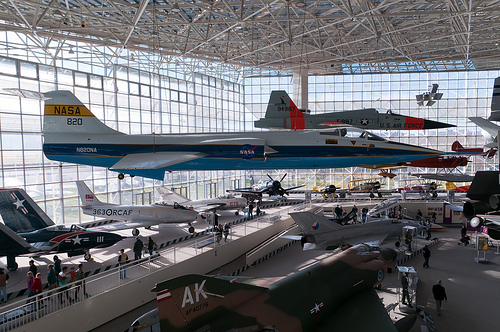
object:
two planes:
[74, 180, 249, 236]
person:
[32, 273, 47, 307]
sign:
[225, 172, 306, 200]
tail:
[41, 90, 128, 176]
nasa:
[45, 105, 95, 116]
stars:
[72, 235, 82, 246]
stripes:
[83, 237, 90, 241]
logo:
[65, 234, 90, 245]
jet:
[0, 187, 136, 270]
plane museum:
[56, 175, 435, 323]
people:
[43, 264, 61, 300]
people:
[133, 237, 145, 264]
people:
[215, 223, 223, 243]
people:
[352, 205, 359, 220]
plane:
[253, 90, 457, 130]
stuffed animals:
[73, 180, 199, 236]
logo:
[9, 192, 29, 215]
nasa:
[240, 144, 258, 161]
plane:
[155, 186, 249, 219]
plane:
[226, 172, 307, 198]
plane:
[345, 177, 385, 198]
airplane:
[254, 89, 457, 131]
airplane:
[39, 90, 484, 181]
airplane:
[280, 211, 428, 252]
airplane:
[149, 242, 387, 332]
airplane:
[76, 180, 199, 229]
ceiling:
[2, 1, 497, 72]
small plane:
[156, 187, 248, 217]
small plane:
[226, 173, 306, 198]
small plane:
[310, 184, 341, 198]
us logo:
[361, 118, 369, 126]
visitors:
[45, 264, 58, 299]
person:
[118, 249, 130, 280]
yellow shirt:
[119, 252, 127, 263]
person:
[431, 279, 448, 317]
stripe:
[43, 143, 444, 159]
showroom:
[0, 0, 500, 330]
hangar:
[0, 53, 500, 332]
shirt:
[32, 277, 43, 292]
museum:
[8, 24, 491, 325]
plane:
[457, 171, 499, 263]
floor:
[81, 202, 496, 330]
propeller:
[260, 173, 289, 197]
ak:
[179, 279, 208, 309]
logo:
[310, 302, 326, 314]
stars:
[239, 143, 258, 161]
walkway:
[25, 192, 313, 264]